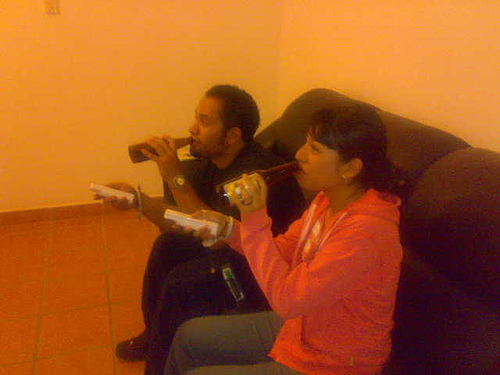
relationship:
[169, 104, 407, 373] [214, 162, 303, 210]
girl drinking beer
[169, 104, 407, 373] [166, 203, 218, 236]
girl holding remote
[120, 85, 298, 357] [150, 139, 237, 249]
man with left arm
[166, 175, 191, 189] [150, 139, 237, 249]
watch on top of left arm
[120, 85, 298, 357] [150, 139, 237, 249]
man has left arm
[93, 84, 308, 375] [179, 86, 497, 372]
man sitting on couch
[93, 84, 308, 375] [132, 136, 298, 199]
man drinking beer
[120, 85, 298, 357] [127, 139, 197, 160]
man drinking beer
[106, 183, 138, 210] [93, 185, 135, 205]
hand holding controller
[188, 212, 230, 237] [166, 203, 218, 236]
hand holding remote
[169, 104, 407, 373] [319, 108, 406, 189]
girl with hair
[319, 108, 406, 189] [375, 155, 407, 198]
hair in pony tail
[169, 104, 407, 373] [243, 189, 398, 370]
girl wearing hoodie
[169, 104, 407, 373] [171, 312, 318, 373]
girl wearing jeans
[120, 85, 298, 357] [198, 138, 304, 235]
man wearing shirt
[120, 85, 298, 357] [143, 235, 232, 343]
man wearing pants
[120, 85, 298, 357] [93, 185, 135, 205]
man holding controller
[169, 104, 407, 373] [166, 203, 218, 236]
girl playing with remote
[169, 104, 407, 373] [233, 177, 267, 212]
girl has hand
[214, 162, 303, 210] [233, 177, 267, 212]
beer in hand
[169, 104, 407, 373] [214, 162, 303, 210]
girl holding beer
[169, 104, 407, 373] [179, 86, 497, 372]
girl sitting on couch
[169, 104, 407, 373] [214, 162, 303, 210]
girl with beer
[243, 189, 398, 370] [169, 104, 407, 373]
hoodie on top of girl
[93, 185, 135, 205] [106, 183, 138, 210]
controller in hand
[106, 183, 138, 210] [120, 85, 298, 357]
hand of man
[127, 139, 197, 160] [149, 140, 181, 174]
beer in hand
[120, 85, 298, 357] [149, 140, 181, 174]
man has hand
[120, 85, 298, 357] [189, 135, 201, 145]
man has mouth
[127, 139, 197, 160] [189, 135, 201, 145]
beer in mouth